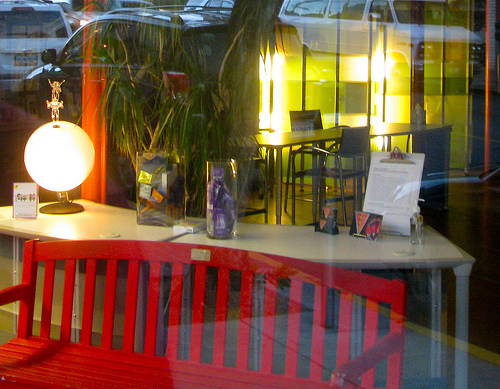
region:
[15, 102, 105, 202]
illuminated lamp on counter top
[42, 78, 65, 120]
golden object on top of lamp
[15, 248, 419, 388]
red wooden bench in room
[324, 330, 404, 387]
red wooden arm rest of bench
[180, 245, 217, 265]
small metal placard on back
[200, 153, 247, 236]
vase filled with object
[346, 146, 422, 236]
blip board with piece of paper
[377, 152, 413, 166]
silver clip on top of board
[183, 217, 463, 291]
white curved table top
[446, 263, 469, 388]
silver and white table leg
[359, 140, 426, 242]
Clip board on table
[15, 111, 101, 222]
Round light on table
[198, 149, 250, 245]
Glass jar on table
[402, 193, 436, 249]
Hand sanitizer on table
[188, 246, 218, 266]
Metal sign on bench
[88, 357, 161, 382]
Wooden bench painted red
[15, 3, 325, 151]
Car reflection in window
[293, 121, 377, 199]
Metal chair near table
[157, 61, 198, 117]
Reflection of a car tail light in window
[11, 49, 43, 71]
Car license plate reflection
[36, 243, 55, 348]
Slab of a red wooden bench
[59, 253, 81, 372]
Slat of a red wooden bench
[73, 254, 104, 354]
Slat of a red wooden bench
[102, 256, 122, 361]
Slat of a red wooden bench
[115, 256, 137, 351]
Slat of a red wooden bench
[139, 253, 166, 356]
Slat of a red wooden bench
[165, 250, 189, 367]
Slat of a red wooden bench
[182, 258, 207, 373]
Slat of a red wooden bench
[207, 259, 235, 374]
Slat of a red wooden bench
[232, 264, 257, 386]
Slat of a red wooden bench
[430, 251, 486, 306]
white table in window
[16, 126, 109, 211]
round lamp on stand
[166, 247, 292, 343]
reflection of objects in window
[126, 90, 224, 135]
green spiky leaves on plant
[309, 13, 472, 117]
reflection of white van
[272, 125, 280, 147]
long dark desk inside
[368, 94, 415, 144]
light shining behind desk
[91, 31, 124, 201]
orange part of wall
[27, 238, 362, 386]
the bench is red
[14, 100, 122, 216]
a round yellow lamp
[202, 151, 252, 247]
jars on the table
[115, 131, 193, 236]
jars on the table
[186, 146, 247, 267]
jars on the table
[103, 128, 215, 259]
jars on the table